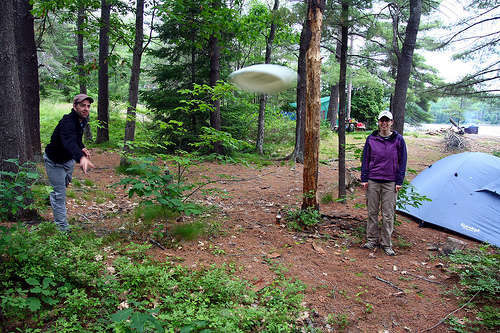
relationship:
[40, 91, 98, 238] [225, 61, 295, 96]
man throwing frisbee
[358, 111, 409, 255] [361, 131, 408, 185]
woman wearing jacket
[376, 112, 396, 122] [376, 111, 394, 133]
hat on head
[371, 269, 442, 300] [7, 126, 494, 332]
twigs are on ground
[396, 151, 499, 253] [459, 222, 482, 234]
tent has logo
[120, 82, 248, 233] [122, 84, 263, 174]
tree have leaves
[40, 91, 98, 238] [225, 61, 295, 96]
man throws frisbee